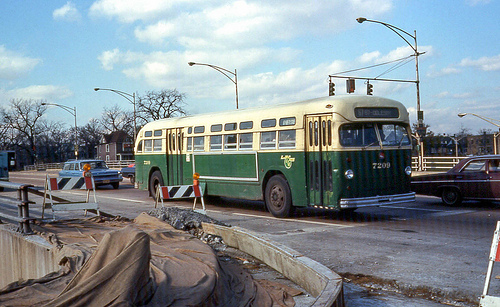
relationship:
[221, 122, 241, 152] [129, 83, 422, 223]
window on bus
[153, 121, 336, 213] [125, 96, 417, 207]
doors on side of bus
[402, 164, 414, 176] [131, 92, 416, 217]
headlight on bus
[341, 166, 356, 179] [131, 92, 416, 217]
headlight on bus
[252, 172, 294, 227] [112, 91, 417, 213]
tire on bus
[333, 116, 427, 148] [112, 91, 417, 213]
windshield of bus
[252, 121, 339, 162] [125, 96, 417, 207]
window on bus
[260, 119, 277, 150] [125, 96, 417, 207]
window on bus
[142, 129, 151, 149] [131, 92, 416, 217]
window on bus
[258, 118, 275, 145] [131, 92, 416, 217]
window on bus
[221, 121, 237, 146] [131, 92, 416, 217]
window on bus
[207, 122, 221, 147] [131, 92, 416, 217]
window on bus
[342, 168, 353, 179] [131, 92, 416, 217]
head light on bus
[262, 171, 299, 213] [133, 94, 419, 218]
wheel on bus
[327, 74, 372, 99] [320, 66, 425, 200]
traffic lights on pole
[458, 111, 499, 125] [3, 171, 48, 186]
street light on road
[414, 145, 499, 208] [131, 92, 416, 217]
car by bus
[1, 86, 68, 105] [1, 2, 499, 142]
clouds in sky